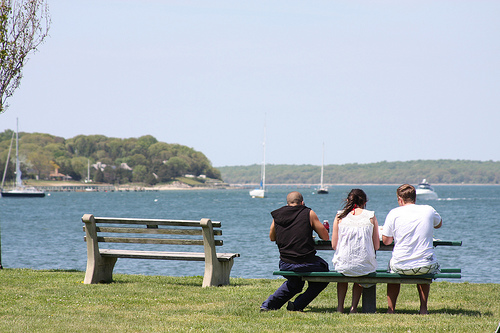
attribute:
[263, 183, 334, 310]
man — bald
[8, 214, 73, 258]
water — calm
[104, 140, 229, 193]
land — full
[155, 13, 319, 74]
sky — blue